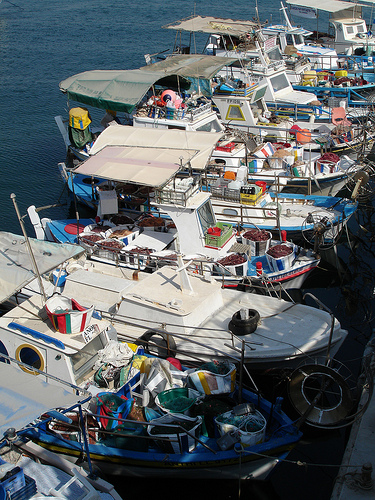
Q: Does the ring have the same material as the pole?
A: Yes, both the ring and the pole are made of metal.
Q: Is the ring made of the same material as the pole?
A: Yes, both the ring and the pole are made of metal.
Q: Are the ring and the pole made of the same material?
A: Yes, both the ring and the pole are made of metal.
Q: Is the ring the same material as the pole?
A: Yes, both the ring and the pole are made of metal.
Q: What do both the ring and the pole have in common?
A: The material, both the ring and the pole are metallic.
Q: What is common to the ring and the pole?
A: The material, both the ring and the pole are metallic.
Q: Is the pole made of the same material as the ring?
A: Yes, both the pole and the ring are made of metal.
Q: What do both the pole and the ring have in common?
A: The material, both the pole and the ring are metallic.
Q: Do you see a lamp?
A: No, there are no lamps.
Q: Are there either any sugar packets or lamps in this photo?
A: No, there are no lamps or sugar packets.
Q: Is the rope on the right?
A: Yes, the rope is on the right of the image.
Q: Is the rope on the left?
A: No, the rope is on the right of the image.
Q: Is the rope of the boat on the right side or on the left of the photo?
A: The rope is on the right of the image.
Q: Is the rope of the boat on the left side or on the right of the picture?
A: The rope is on the right of the image.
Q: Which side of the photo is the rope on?
A: The rope is on the right of the image.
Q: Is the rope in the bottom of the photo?
A: Yes, the rope is in the bottom of the image.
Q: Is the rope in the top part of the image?
A: No, the rope is in the bottom of the image.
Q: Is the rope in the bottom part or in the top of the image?
A: The rope is in the bottom of the image.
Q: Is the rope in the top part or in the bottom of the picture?
A: The rope is in the bottom of the image.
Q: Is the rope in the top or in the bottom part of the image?
A: The rope is in the bottom of the image.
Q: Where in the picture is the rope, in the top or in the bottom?
A: The rope is in the bottom of the image.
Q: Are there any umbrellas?
A: No, there are no umbrellas.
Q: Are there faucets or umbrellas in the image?
A: No, there are no umbrellas or faucets.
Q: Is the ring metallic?
A: Yes, the ring is metallic.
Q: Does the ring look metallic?
A: Yes, the ring is metallic.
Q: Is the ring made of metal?
A: Yes, the ring is made of metal.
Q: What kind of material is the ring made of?
A: The ring is made of metal.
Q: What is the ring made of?
A: The ring is made of metal.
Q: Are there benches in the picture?
A: No, there are no benches.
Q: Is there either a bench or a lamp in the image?
A: No, there are no benches or lamps.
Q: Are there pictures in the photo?
A: No, there are no pictures.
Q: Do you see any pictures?
A: No, there are no pictures.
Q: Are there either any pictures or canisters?
A: No, there are no pictures or canisters.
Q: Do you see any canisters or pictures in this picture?
A: No, there are no pictures or canisters.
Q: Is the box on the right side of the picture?
A: Yes, the box is on the right of the image.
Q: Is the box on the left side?
A: No, the box is on the right of the image.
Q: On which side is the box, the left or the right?
A: The box is on the right of the image.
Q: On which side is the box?
A: The box is on the right of the image.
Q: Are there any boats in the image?
A: Yes, there is a boat.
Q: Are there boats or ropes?
A: Yes, there is a boat.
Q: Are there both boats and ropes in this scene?
A: Yes, there are both a boat and a rope.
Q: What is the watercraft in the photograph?
A: The watercraft is a boat.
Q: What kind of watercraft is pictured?
A: The watercraft is a boat.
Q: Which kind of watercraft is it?
A: The watercraft is a boat.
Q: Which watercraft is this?
A: This is a boat.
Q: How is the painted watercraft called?
A: The watercraft is a boat.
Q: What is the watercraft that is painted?
A: The watercraft is a boat.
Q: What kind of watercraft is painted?
A: The watercraft is a boat.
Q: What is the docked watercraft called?
A: The watercraft is a boat.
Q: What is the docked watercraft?
A: The watercraft is a boat.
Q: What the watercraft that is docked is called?
A: The watercraft is a boat.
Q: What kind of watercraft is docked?
A: The watercraft is a boat.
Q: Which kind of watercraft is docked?
A: The watercraft is a boat.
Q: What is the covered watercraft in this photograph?
A: The watercraft is a boat.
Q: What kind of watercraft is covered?
A: The watercraft is a boat.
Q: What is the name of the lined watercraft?
A: The watercraft is a boat.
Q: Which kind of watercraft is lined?
A: The watercraft is a boat.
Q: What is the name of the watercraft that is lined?
A: The watercraft is a boat.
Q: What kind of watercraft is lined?
A: The watercraft is a boat.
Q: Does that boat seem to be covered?
A: Yes, the boat is covered.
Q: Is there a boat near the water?
A: Yes, there is a boat near the water.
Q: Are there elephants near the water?
A: No, there is a boat near the water.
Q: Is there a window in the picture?
A: Yes, there is a window.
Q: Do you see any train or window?
A: Yes, there is a window.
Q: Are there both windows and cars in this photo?
A: No, there is a window but no cars.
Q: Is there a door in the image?
A: No, there are no doors.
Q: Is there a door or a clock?
A: No, there are no doors or clocks.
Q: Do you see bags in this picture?
A: Yes, there is a bag.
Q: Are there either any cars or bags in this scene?
A: Yes, there is a bag.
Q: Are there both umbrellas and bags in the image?
A: No, there is a bag but no umbrellas.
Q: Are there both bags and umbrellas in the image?
A: No, there is a bag but no umbrellas.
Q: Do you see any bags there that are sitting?
A: Yes, there is a bag that is sitting.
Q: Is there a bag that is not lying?
A: Yes, there is a bag that is sitting.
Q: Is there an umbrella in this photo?
A: No, there are no umbrellas.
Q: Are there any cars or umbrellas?
A: No, there are no umbrellas or cars.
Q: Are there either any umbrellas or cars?
A: No, there are no umbrellas or cars.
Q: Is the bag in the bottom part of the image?
A: Yes, the bag is in the bottom of the image.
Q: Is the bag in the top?
A: No, the bag is in the bottom of the image.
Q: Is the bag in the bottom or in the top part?
A: The bag is in the bottom of the image.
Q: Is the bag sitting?
A: Yes, the bag is sitting.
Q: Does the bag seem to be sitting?
A: Yes, the bag is sitting.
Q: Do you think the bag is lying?
A: No, the bag is sitting.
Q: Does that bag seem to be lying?
A: No, the bag is sitting.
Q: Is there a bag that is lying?
A: No, there is a bag but it is sitting.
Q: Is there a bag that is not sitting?
A: No, there is a bag but it is sitting.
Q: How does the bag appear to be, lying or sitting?
A: The bag is sitting.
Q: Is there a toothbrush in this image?
A: No, there are no toothbrushes.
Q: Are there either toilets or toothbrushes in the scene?
A: No, there are no toothbrushes or toilets.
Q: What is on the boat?
A: The basket is on the boat.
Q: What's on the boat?
A: The basket is on the boat.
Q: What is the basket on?
A: The basket is on the boat.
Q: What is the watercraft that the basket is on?
A: The watercraft is a boat.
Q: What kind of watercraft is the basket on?
A: The basket is on the boat.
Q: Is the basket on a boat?
A: Yes, the basket is on a boat.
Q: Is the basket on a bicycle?
A: No, the basket is on a boat.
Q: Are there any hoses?
A: No, there are no hoses.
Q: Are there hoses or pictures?
A: No, there are no hoses or pictures.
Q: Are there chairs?
A: Yes, there is a chair.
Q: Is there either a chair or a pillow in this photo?
A: Yes, there is a chair.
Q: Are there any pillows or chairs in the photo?
A: Yes, there is a chair.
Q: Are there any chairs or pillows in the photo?
A: Yes, there is a chair.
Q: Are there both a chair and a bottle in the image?
A: No, there is a chair but no bottles.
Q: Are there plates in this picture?
A: No, there are no plates.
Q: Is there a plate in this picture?
A: No, there are no plates.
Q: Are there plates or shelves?
A: No, there are no plates or shelves.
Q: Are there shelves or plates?
A: No, there are no plates or shelves.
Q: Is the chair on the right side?
A: Yes, the chair is on the right of the image.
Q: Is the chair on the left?
A: No, the chair is on the right of the image.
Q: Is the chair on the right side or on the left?
A: The chair is on the right of the image.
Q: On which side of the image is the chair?
A: The chair is on the right of the image.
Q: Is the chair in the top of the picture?
A: Yes, the chair is in the top of the image.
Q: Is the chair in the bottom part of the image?
A: No, the chair is in the top of the image.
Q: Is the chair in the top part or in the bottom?
A: The chair is in the top of the image.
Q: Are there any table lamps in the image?
A: No, there are no table lamps.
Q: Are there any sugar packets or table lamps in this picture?
A: No, there are no table lamps or sugar packets.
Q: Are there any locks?
A: No, there are no locks.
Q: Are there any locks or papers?
A: No, there are no locks or papers.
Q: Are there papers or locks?
A: No, there are no locks or papers.